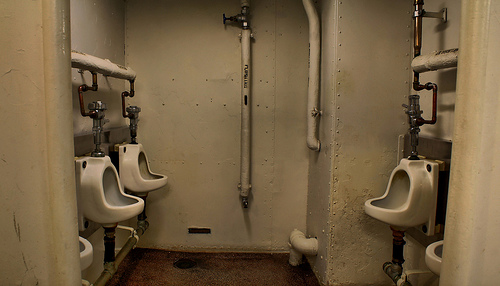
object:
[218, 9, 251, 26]
handle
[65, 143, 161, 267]
urinals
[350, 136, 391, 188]
ground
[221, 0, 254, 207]
pipe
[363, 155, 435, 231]
urinal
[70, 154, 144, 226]
urinal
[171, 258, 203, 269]
drain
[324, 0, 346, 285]
corner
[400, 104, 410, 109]
flush handle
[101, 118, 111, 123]
flush handle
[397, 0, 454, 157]
giraffe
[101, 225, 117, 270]
pipe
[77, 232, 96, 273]
urinal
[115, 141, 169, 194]
urinal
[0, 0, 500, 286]
wall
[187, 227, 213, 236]
hole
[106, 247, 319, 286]
dirty floor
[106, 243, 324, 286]
floor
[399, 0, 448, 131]
pipe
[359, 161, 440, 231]
toilet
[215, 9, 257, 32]
valve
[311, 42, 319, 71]
white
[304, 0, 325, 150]
pipe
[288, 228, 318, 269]
pipe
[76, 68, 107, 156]
pipes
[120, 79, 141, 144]
pipes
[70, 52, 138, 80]
pipes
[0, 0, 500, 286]
waall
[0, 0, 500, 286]
room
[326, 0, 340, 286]
rivets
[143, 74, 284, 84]
rivets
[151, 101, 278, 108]
rivets